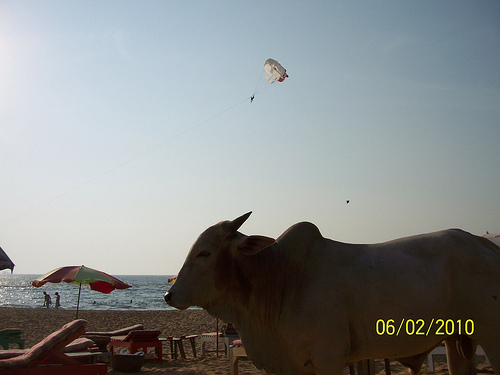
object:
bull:
[174, 228, 494, 369]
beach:
[152, 315, 175, 328]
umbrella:
[51, 264, 116, 316]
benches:
[116, 323, 203, 360]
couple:
[35, 289, 61, 304]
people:
[55, 295, 67, 312]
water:
[139, 287, 154, 300]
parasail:
[263, 55, 285, 84]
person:
[241, 93, 258, 107]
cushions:
[111, 328, 125, 339]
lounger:
[130, 332, 160, 357]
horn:
[231, 210, 246, 229]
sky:
[94, 7, 138, 32]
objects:
[161, 269, 178, 286]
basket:
[1, 333, 21, 347]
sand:
[125, 316, 151, 324]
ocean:
[125, 294, 145, 302]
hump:
[306, 225, 415, 258]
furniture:
[123, 325, 201, 355]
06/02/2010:
[368, 314, 473, 342]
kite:
[273, 67, 290, 84]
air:
[305, 54, 376, 115]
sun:
[8, 280, 30, 291]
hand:
[41, 298, 46, 302]